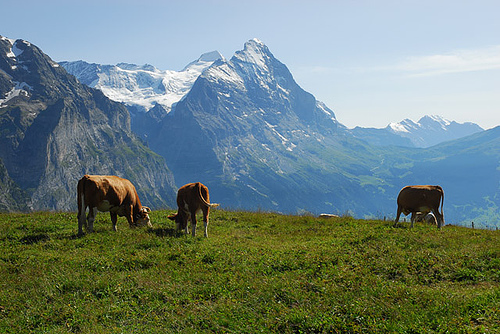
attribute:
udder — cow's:
[92, 202, 112, 214]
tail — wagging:
[192, 180, 224, 211]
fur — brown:
[114, 180, 129, 192]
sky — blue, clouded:
[0, 2, 498, 129]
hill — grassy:
[4, 205, 498, 332]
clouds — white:
[0, 1, 498, 131]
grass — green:
[188, 246, 420, 318]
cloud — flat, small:
[360, 43, 474, 128]